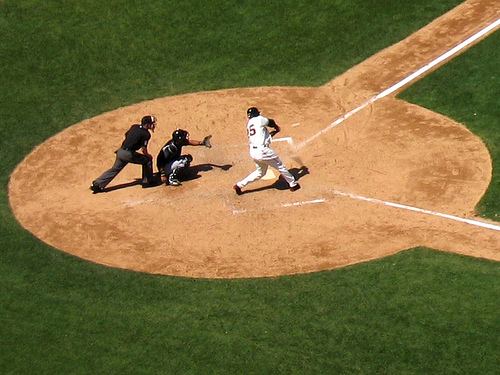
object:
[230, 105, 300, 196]
people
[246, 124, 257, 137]
number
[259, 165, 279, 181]
base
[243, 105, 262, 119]
helmet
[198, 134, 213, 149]
glove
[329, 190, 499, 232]
line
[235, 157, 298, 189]
pants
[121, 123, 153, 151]
sleeve shirt